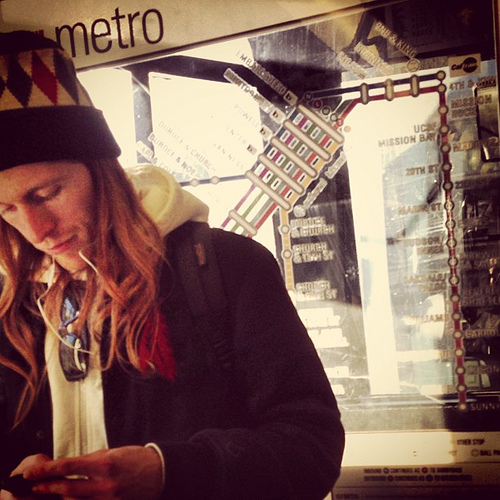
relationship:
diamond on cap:
[27, 46, 63, 103] [0, 24, 125, 175]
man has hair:
[5, 25, 355, 488] [2, 154, 179, 428]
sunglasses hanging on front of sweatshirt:
[55, 275, 95, 382] [35, 261, 118, 455]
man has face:
[5, 25, 355, 488] [0, 158, 95, 274]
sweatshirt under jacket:
[35, 261, 118, 455] [4, 224, 353, 490]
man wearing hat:
[5, 25, 355, 488] [4, 25, 120, 167]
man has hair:
[5, 25, 355, 488] [70, 155, 179, 378]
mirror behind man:
[121, 66, 481, 406] [5, 25, 355, 488]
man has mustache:
[5, 25, 355, 488] [31, 228, 76, 242]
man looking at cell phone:
[5, 25, 355, 488] [4, 467, 63, 498]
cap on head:
[0, 24, 125, 175] [1, 21, 132, 275]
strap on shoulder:
[171, 218, 232, 334] [166, 222, 317, 380]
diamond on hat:
[27, 46, 63, 103] [4, 25, 120, 167]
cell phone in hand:
[4, 467, 63, 498] [49, 443, 166, 495]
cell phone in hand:
[4, 467, 63, 498] [7, 450, 55, 493]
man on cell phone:
[0, 21, 353, 486] [4, 471, 62, 496]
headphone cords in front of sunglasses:
[31, 241, 116, 358] [55, 275, 95, 382]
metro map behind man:
[123, 51, 498, 418] [0, 21, 353, 486]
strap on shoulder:
[171, 219, 232, 343] [159, 218, 297, 358]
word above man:
[52, 2, 171, 63] [0, 21, 353, 486]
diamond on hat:
[4, 52, 33, 108] [4, 25, 120, 167]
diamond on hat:
[50, 42, 80, 98] [4, 25, 120, 167]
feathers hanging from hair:
[130, 308, 183, 384] [70, 155, 179, 378]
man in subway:
[5, 25, 355, 488] [1, 5, 484, 493]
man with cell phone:
[0, 21, 353, 486] [21, 435, 138, 498]